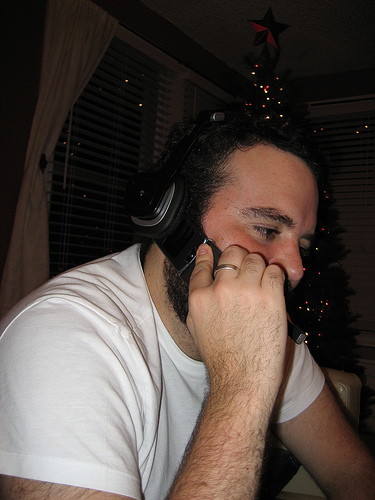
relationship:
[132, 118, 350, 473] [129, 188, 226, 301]
man using cellphone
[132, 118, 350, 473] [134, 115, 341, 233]
man wearing headphones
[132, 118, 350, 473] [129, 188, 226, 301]
man holding cellphone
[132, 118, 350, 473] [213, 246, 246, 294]
man wearing ring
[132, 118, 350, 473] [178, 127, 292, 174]
man has black hair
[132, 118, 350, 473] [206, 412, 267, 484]
man has hairy arm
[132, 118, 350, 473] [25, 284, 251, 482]
man in white shirt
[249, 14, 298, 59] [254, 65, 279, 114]
star atop christmas tree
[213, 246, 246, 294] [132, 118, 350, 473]
ring belongs to man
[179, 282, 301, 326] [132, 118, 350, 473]
knuckle of man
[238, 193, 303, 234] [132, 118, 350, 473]
eyebrow of man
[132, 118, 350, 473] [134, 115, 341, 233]
man listening to headphones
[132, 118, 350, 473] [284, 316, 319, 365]
man holding microphone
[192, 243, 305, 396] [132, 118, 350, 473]
hand of man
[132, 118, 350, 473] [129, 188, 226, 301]
man on cellphone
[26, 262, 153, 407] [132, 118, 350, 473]
shoulder of man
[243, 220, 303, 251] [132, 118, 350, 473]
eye of man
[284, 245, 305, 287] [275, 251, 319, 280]
part of nose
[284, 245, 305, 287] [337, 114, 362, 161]
part of mini blinds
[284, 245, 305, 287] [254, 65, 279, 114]
part of christmas tree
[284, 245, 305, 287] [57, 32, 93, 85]
part of curtains